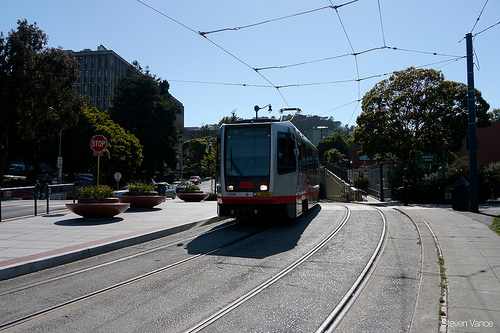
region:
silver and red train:
[211, 128, 306, 214]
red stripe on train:
[220, 185, 285, 202]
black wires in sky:
[218, 12, 373, 87]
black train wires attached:
[220, 5, 343, 90]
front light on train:
[257, 178, 274, 193]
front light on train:
[227, 185, 235, 191]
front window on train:
[227, 122, 274, 179]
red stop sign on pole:
[87, 131, 114, 153]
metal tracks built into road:
[260, 220, 381, 310]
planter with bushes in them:
[66, 183, 135, 220]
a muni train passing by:
[201, 99, 338, 233]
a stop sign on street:
[82, 132, 117, 214]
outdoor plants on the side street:
[63, 170, 215, 227]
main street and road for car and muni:
[7, 164, 497, 331]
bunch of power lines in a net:
[200, 33, 492, 125]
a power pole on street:
[449, 3, 495, 226]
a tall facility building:
[40, 36, 197, 188]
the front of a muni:
[213, 107, 302, 227]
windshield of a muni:
[214, 120, 281, 200]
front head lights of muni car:
[225, 180, 273, 195]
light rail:
[207, 110, 316, 236]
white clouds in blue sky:
[92, 6, 131, 33]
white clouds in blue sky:
[178, 32, 218, 69]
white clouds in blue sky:
[244, 10, 313, 48]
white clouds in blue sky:
[66, 13, 122, 43]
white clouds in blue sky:
[193, 61, 214, 86]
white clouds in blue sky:
[316, 21, 357, 60]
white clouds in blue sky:
[362, 19, 418, 44]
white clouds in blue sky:
[235, 18, 302, 67]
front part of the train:
[194, 98, 307, 233]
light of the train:
[250, 175, 272, 200]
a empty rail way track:
[232, 236, 404, 316]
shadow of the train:
[201, 218, 295, 279]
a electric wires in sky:
[216, 2, 463, 117]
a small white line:
[419, 203, 461, 330]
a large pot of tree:
[87, 180, 139, 230]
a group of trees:
[26, 73, 184, 227]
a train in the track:
[194, 94, 386, 294]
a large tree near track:
[354, 76, 497, 221]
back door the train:
[201, 110, 311, 238]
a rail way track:
[242, 251, 373, 330]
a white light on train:
[253, 179, 277, 194]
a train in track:
[194, 113, 301, 225]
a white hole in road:
[418, 223, 449, 330]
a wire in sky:
[202, 0, 484, 92]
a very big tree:
[361, 62, 492, 168]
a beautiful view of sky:
[81, 5, 482, 122]